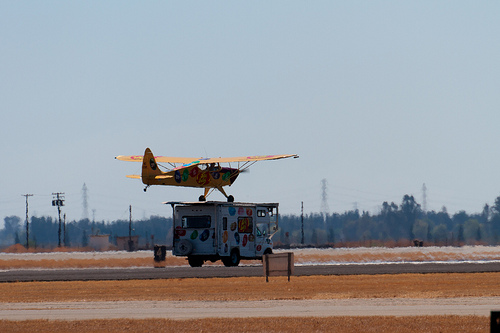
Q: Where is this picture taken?
A: Day time.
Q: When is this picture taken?
A: On air strip.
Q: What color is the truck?
A: White.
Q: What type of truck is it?
A: Ice cream truck.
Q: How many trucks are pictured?
A: One.